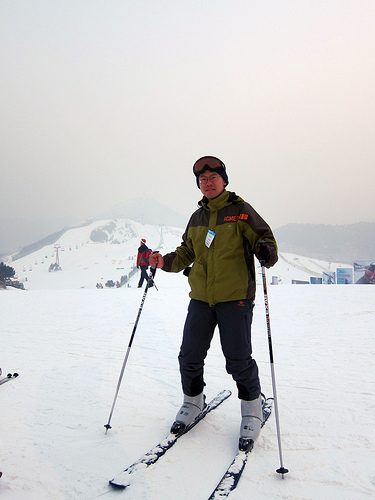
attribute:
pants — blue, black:
[179, 295, 258, 398]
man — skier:
[154, 150, 266, 440]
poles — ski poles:
[94, 261, 291, 477]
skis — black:
[101, 391, 278, 498]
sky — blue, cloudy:
[1, 1, 372, 263]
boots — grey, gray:
[180, 393, 262, 440]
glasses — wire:
[197, 174, 224, 184]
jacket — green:
[166, 204, 272, 301]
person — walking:
[137, 238, 156, 287]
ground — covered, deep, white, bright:
[4, 290, 374, 499]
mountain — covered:
[8, 218, 368, 497]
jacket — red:
[137, 247, 151, 263]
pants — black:
[135, 264, 154, 288]